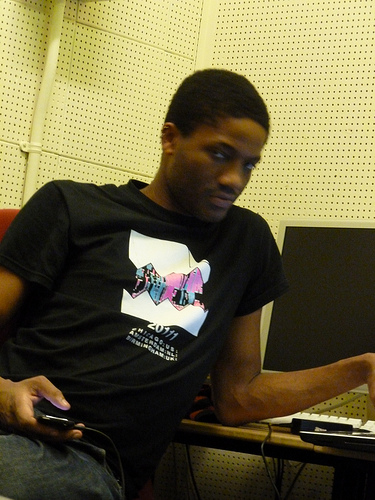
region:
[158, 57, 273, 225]
a young man's face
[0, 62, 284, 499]
a young man sitting down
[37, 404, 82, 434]
a charging phone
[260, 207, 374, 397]
part of a computer monitor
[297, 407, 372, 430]
part of a computer keyboard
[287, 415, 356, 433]
laptop power chord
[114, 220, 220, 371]
male t-shirt art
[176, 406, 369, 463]
top of a computer desk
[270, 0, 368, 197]
perforated divider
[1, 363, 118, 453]
a hand holding a charding device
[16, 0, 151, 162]
White pegboard enclosed cubicle.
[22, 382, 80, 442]
Cell phone lit up in man's hand.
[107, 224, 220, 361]
Black tee shirt with a white, purple and blue design.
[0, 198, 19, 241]
Red office chair in the background.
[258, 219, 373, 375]
Large monitor with a twenty one inch screen.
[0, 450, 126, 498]
Blue jeans that appear black.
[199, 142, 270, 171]
Suspicious eyes following the camera.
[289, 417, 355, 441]
Electrical connection for desk top printer.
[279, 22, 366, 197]
A zillion holes in the side of the cubicle.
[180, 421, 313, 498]
Computer wires tangled under a computer desk.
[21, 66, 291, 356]
a man wearing a black t-shirt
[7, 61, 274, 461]
a man holding a cell phone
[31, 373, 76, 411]
the thumb of a man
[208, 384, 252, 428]
the elbow of a man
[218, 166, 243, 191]
the nose of a man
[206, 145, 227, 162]
the eye of a man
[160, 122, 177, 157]
the ear of a man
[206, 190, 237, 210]
the mouth of a man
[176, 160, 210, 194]
the cheek of a man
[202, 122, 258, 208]
the face of a man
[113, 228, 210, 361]
logo on front of shirt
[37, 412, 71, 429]
cell phone in hand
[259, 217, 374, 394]
computer monitor on desk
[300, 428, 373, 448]
bottom of laptop on desk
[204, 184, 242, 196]
little mustache on man's lip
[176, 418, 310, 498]
bunch of cords hanging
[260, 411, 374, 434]
computer keyboard on desk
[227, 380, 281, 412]
veins popping out of arm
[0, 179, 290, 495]
black shirt on man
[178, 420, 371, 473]
desk with stuff on it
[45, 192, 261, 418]
the shirt is black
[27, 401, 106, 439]
the phone is on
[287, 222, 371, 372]
the scrren is off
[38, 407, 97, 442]
the phone has a cable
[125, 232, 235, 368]
the shirt has an image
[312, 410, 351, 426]
the keyboard is white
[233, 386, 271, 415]
veins are on the hand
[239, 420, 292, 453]
the table is wooden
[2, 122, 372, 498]
the guy is looking at the camera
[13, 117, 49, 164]
pipe is on the wall